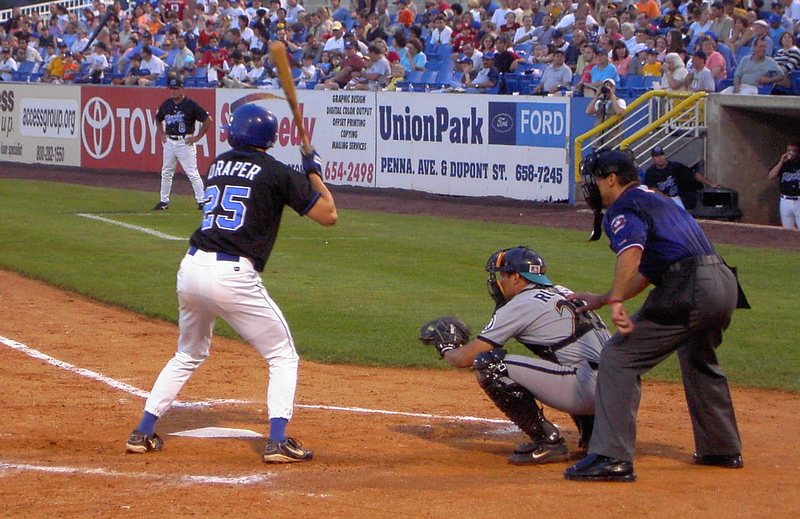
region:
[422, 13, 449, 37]
a person is sitting down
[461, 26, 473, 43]
a person is sitting down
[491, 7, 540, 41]
p a person is sitting down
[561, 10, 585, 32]
a person is sitting down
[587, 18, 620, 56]
a person is sitting down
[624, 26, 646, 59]
a person is sitting down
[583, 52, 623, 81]
a person is sitting down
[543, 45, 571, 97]
a person is sitting down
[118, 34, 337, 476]
The player that is batting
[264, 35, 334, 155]
The wooden bat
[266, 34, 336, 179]
A wooden bat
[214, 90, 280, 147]
The blue helmet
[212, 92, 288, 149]
A blue helmet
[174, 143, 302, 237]
The black and blue jersey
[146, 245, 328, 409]
The batter's white pants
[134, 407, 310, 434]
The batter's blue socks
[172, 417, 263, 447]
The white home base plate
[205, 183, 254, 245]
shirt has blue numbers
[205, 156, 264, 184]
shirt has white letters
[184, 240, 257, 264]
belt on batter is blue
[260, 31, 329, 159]
bat held by batter is brown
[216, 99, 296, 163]
helmet on batter is blue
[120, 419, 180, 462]
shoes on batter are white and black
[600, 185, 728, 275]
umpire is wearing blue shirt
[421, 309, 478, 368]
catcher is wearing black glove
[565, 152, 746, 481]
Umpire calling the game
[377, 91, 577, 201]
Sign advertising a ford dealership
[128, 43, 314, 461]
Batter holding a baseball bat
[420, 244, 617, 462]
Catcher waiting for the ball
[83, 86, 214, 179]
Sign advertising Toyota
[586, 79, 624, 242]
Man taking pictures of the game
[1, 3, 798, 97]
Crowd watching the baseball game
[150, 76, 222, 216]
First base coach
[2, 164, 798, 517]
Baseball field for playing baseball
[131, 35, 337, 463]
man holding a wooden bat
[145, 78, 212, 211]
man with hands on hips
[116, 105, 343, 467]
man wearing white pants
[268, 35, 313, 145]
a brown wooden bat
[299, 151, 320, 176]
a leather batting glove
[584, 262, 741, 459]
a pair of grey pants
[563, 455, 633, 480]
a man's black shoe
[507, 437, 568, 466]
a black athletic shoe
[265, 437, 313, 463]
a black and white athletic shoe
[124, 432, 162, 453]
a black and white athletic shoe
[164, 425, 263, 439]
a white home base plate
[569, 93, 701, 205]
a short stair case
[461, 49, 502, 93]
A person is sitting down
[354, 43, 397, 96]
A person is sitting down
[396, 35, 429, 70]
A person is sitting down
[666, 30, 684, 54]
A person is sitting down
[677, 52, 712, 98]
A person is sitting down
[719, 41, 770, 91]
A person is sitting down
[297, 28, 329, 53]
A person is sitting down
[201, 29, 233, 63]
A person is sitting down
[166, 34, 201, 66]
A person is sitting down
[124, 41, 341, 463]
a baseball player at bat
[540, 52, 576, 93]
A person is sitting down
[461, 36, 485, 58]
A person is sitting down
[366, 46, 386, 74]
A person is sitting down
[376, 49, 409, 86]
A person is sitting down